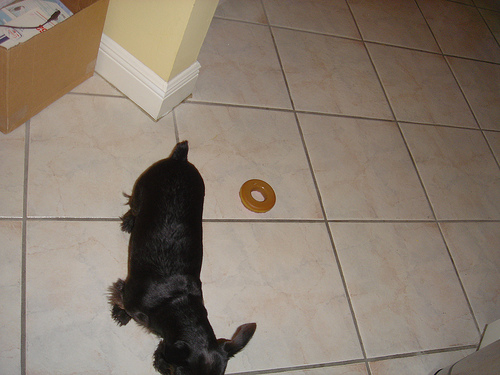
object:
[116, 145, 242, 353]
dog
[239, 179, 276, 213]
toy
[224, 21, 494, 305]
floor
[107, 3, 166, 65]
wall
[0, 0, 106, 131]
box